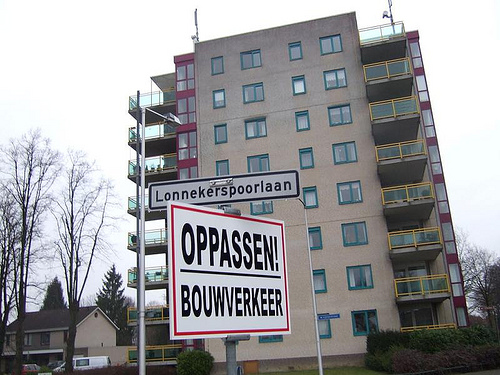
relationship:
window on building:
[241, 48, 262, 69] [128, 11, 470, 373]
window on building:
[243, 82, 265, 104] [128, 11, 470, 373]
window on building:
[244, 116, 267, 139] [128, 11, 470, 373]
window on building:
[293, 75, 305, 94] [128, 11, 470, 373]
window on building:
[297, 111, 310, 131] [128, 11, 470, 373]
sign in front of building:
[166, 201, 290, 340] [128, 11, 470, 373]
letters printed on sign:
[178, 222, 284, 316] [166, 201, 290, 340]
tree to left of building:
[39, 147, 129, 374] [128, 11, 470, 373]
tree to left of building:
[0, 125, 62, 374] [128, 11, 470, 373]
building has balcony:
[128, 11, 470, 373] [127, 71, 178, 126]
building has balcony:
[128, 11, 470, 373] [129, 120, 178, 159]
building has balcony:
[128, 11, 470, 373] [128, 151, 178, 187]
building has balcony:
[128, 11, 470, 373] [358, 21, 408, 63]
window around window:
[290, 73, 307, 96] [293, 75, 305, 94]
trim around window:
[295, 109, 313, 130] [297, 111, 310, 131]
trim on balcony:
[361, 55, 411, 80] [361, 57, 412, 101]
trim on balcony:
[369, 94, 422, 124] [368, 96, 422, 144]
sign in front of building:
[145, 168, 300, 210] [128, 11, 470, 373]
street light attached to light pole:
[144, 108, 182, 128] [140, 105, 183, 373]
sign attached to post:
[166, 201, 290, 340] [220, 336, 250, 374]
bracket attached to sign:
[209, 176, 233, 187] [145, 168, 300, 210]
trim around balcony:
[361, 55, 411, 80] [361, 57, 412, 101]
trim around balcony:
[369, 94, 422, 124] [368, 96, 422, 144]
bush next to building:
[366, 326, 499, 372] [128, 11, 470, 373]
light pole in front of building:
[140, 105, 183, 373] [128, 11, 470, 373]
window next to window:
[212, 56, 225, 76] [241, 48, 262, 69]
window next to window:
[241, 48, 262, 69] [288, 41, 303, 61]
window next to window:
[288, 41, 303, 61] [319, 34, 343, 55]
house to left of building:
[1, 305, 120, 371] [128, 11, 470, 373]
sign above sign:
[145, 168, 300, 210] [166, 201, 290, 340]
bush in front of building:
[174, 348, 215, 374] [128, 11, 470, 373]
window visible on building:
[314, 269, 325, 293] [128, 11, 470, 373]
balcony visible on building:
[375, 139, 427, 183] [128, 11, 470, 373]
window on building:
[212, 56, 225, 76] [128, 11, 470, 373]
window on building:
[288, 41, 303, 61] [128, 11, 470, 373]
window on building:
[319, 34, 343, 55] [128, 11, 470, 373]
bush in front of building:
[366, 326, 499, 372] [128, 11, 470, 373]